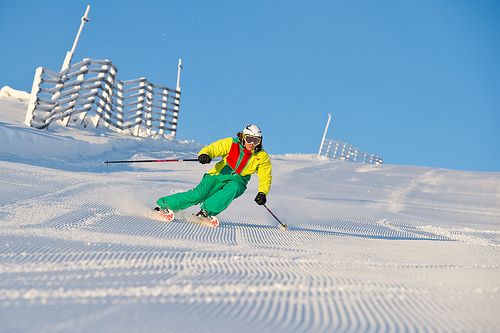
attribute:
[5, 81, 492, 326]
snow — smooth, white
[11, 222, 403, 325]
lines — groovy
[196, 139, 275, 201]
jacket — yellow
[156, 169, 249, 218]
pants — green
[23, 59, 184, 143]
fence — wooden, white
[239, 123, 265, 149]
helmet — white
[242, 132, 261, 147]
goggles — white, yellow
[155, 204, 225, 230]
skis — pair, red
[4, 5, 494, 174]
bright — blue, clear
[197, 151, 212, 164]
gloves — black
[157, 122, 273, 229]
outfit — colorful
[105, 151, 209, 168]
pole — black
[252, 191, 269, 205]
glove — black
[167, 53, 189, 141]
wood — tall